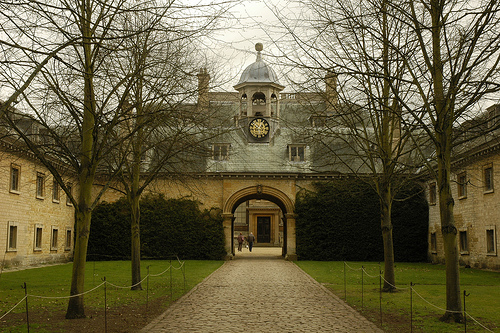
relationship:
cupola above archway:
[252, 39, 268, 59] [222, 179, 297, 259]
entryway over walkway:
[222, 179, 297, 259] [132, 248, 394, 333]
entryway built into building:
[222, 179, 297, 259] [75, 38, 429, 265]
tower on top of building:
[233, 43, 284, 145] [75, 38, 429, 265]